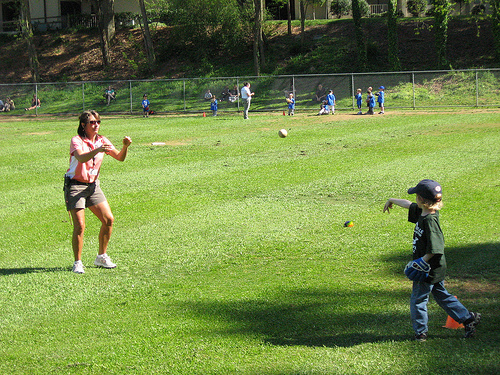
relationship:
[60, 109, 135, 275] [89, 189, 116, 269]
woman has leg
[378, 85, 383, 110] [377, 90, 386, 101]
child in shirt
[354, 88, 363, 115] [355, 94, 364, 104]
kid in shirt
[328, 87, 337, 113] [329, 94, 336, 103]
child in shirt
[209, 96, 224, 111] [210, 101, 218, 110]
child in shirt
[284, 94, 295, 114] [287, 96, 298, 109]
child in shirt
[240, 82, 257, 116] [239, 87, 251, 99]
woman in top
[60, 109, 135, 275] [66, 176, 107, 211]
woman in shorts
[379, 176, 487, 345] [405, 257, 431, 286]
boy with glove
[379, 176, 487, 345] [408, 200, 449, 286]
boy wearing t-shirt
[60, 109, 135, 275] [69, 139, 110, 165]
woman with arm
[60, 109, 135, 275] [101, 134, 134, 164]
woman with arm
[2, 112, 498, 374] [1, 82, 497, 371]
field of grass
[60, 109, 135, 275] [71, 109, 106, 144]
woman in hair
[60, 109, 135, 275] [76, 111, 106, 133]
woman wearing sunglasses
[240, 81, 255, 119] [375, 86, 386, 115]
woman coaching child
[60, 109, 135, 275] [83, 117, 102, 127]
woman wearing sunglasses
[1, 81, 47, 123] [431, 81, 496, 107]
people outside of fence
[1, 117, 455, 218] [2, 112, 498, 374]
stripes along field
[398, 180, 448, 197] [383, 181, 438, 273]
cap on boy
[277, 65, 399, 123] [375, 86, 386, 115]
group of child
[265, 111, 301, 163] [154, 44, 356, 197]
ball in air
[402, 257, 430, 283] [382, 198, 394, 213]
baseball glove on hand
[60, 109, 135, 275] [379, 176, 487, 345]
woman teaches boy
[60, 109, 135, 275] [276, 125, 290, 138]
woman throws ball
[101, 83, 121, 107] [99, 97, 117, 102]
woman sits in chair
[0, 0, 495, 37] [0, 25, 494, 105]
homes on top of hill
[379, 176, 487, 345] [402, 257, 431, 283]
boy wears baseball glove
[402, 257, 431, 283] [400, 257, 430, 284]
baseball glove on hand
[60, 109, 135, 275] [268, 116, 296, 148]
woman catches ball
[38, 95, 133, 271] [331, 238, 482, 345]
woman has legs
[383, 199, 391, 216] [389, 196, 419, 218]
hand has extended arm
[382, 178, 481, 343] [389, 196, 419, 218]
boy has extended arm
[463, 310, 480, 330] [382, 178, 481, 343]
shoe of boy